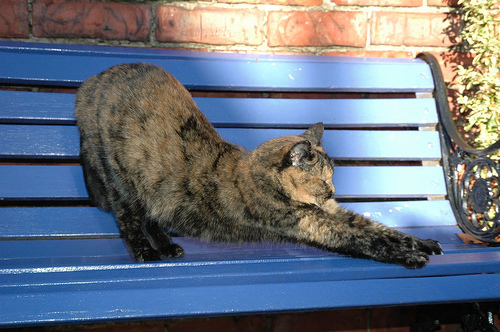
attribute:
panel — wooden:
[0, 50, 434, 91]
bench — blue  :
[2, 37, 496, 322]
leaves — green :
[463, 89, 488, 133]